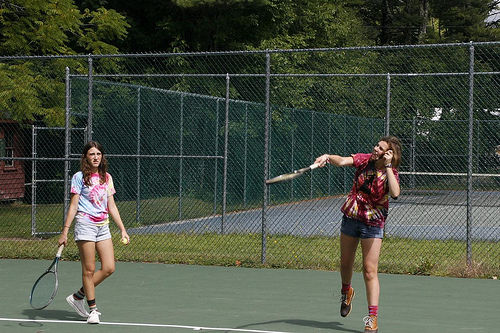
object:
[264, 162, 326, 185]
tennis racket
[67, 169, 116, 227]
shirt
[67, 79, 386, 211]
wall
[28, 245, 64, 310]
tennis racket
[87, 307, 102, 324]
white shoe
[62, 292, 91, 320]
white shoe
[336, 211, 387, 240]
colored shorts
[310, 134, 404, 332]
lady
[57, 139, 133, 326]
partner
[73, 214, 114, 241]
shorts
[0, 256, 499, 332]
tennis court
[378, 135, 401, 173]
hair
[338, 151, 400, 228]
shirt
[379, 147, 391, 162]
cell phone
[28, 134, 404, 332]
game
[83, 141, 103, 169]
head